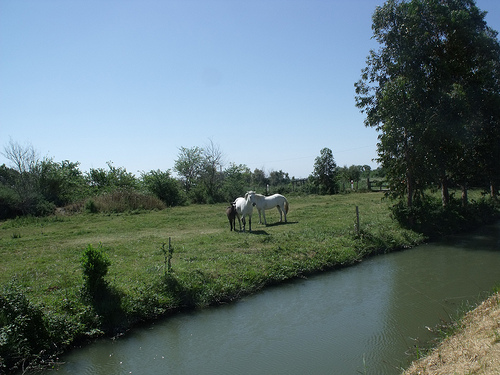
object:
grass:
[407, 287, 499, 373]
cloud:
[24, 135, 387, 168]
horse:
[252, 193, 288, 224]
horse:
[234, 192, 256, 232]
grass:
[2, 169, 396, 315]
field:
[0, 180, 397, 327]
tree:
[354, 0, 500, 218]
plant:
[0, 243, 190, 347]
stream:
[41, 217, 498, 375]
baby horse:
[226, 203, 236, 231]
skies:
[0, 0, 376, 178]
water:
[33, 241, 500, 375]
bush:
[57, 240, 134, 324]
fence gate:
[368, 178, 394, 191]